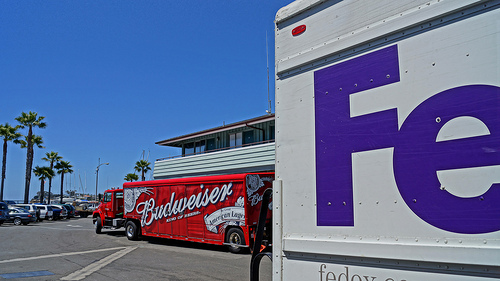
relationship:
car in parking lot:
[6, 205, 36, 226] [0, 213, 271, 279]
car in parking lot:
[17, 202, 41, 220] [0, 213, 271, 279]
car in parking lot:
[48, 202, 69, 217] [0, 213, 271, 279]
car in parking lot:
[49, 204, 76, 217] [0, 213, 271, 279]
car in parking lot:
[71, 202, 90, 215] [0, 213, 271, 279]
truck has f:
[249, 0, 498, 280] [312, 44, 399, 227]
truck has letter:
[249, 0, 498, 280] [391, 82, 499, 235]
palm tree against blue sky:
[56, 157, 71, 204] [59, 12, 232, 115]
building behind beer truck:
[148, 114, 279, 162] [91, 172, 275, 254]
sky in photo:
[1, 0, 273, 195] [1, 2, 498, 278]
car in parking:
[75, 202, 94, 218] [1, 200, 90, 223]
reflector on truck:
[281, 16, 318, 50] [273, 1, 498, 279]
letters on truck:
[135, 177, 302, 217] [120, 157, 340, 261]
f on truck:
[312, 44, 399, 227] [80, 162, 274, 271]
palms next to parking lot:
[0, 109, 152, 204] [0, 213, 271, 279]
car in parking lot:
[3, 207, 36, 226] [0, 187, 284, 279]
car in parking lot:
[17, 198, 52, 223] [0, 187, 284, 279]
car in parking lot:
[41, 198, 76, 221] [0, 187, 284, 279]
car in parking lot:
[49, 204, 76, 217] [0, 187, 284, 279]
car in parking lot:
[75, 202, 94, 218] [0, 187, 284, 279]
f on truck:
[312, 42, 399, 224] [273, 1, 498, 279]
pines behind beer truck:
[117, 156, 153, 182] [91, 172, 275, 254]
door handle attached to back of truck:
[243, 186, 275, 279] [249, 0, 498, 280]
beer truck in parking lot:
[96, 181, 266, 245] [0, 213, 271, 279]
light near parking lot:
[84, 148, 114, 237] [0, 213, 271, 279]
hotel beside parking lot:
[152, 106, 278, 178] [0, 213, 271, 279]